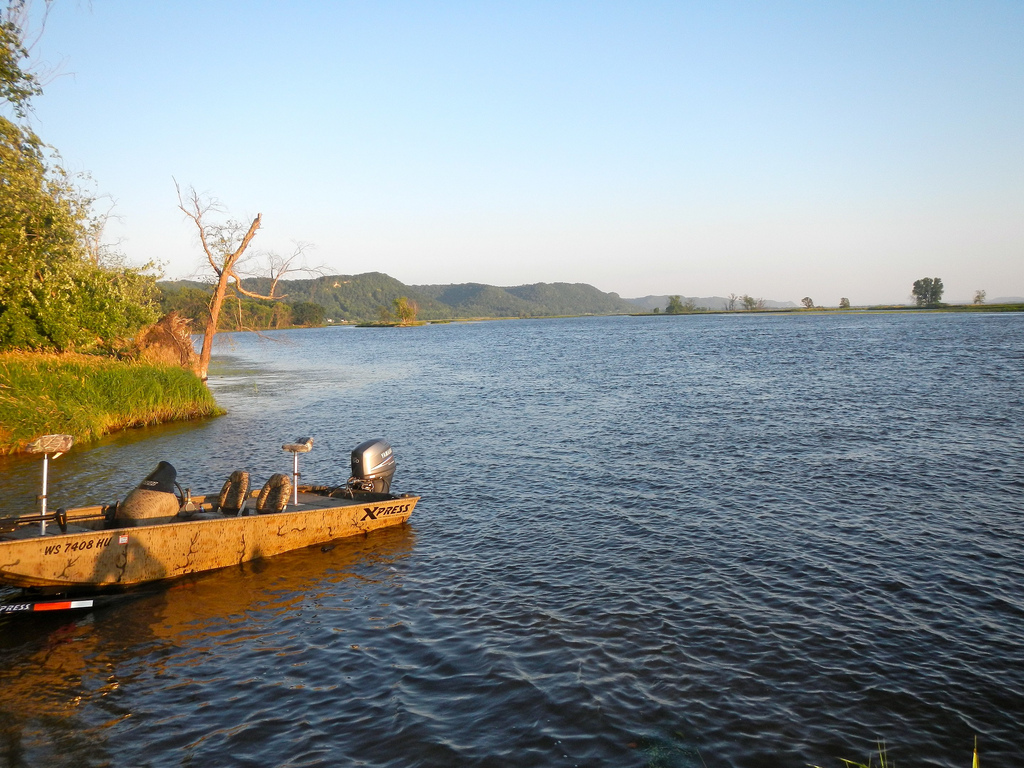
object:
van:
[717, 733, 901, 750]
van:
[605, 733, 941, 765]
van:
[767, 738, 936, 760]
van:
[681, 716, 861, 738]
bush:
[0, 121, 153, 357]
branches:
[180, 176, 298, 306]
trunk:
[129, 301, 212, 367]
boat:
[0, 432, 424, 616]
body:
[521, 362, 945, 683]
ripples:
[476, 557, 879, 718]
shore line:
[24, 370, 227, 452]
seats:
[217, 469, 293, 516]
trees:
[0, 0, 173, 360]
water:
[525, 432, 865, 723]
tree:
[175, 191, 329, 382]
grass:
[0, 363, 184, 446]